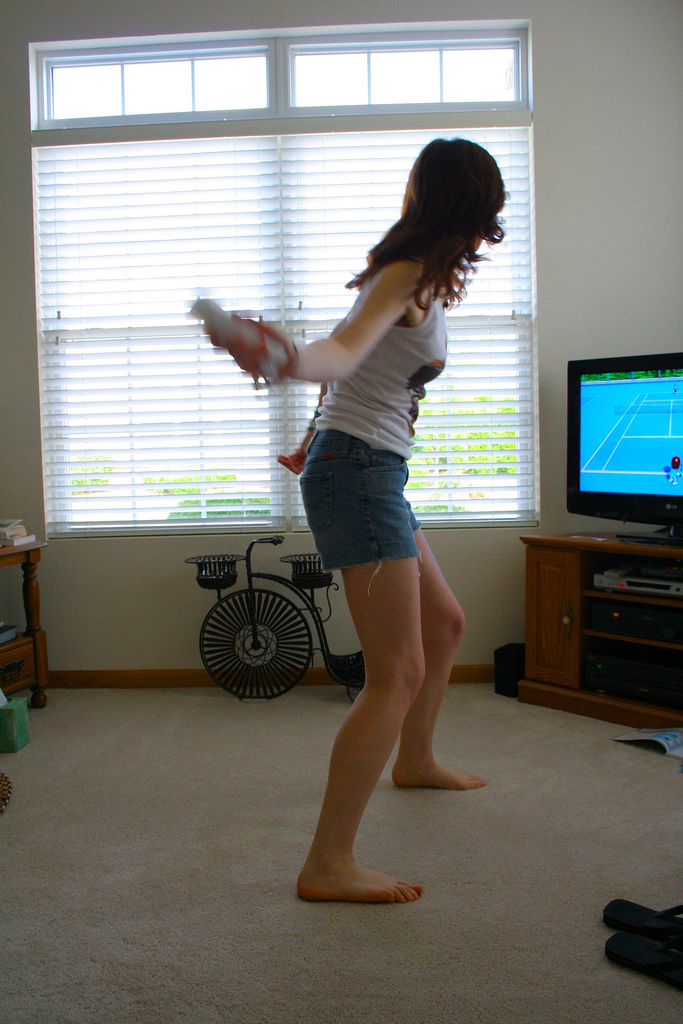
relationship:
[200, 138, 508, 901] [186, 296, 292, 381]
lady holding remote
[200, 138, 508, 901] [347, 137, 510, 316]
lady has hair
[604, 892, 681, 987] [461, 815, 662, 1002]
slippers on road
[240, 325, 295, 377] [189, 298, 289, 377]
hand hold remote